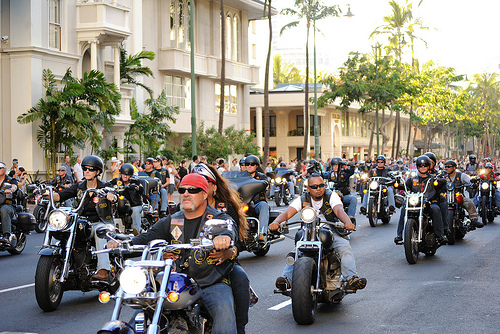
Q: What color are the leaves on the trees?
A: Green.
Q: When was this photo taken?
A: Day time.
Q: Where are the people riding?
A: The street.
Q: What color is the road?
A: Black.